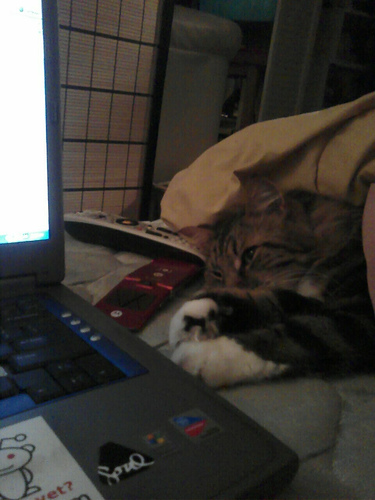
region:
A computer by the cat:
[0, 1, 300, 498]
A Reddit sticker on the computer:
[1, 413, 105, 499]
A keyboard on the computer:
[1, 293, 125, 419]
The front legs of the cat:
[170, 288, 355, 382]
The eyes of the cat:
[213, 245, 258, 278]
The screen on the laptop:
[0, 1, 48, 244]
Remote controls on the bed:
[64, 209, 205, 333]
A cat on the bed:
[166, 167, 373, 383]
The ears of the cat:
[177, 169, 285, 253]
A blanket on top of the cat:
[160, 93, 372, 232]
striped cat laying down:
[177, 186, 351, 361]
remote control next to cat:
[67, 203, 334, 294]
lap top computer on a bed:
[8, 41, 122, 486]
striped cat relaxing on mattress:
[189, 200, 322, 316]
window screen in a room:
[63, 5, 186, 105]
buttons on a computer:
[12, 302, 81, 375]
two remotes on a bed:
[72, 200, 190, 321]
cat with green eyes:
[182, 218, 296, 279]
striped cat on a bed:
[197, 209, 332, 281]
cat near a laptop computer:
[167, 168, 310, 485]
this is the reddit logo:
[0, 431, 39, 497]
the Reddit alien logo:
[1, 428, 39, 498]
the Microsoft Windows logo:
[140, 424, 169, 448]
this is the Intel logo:
[171, 412, 204, 425]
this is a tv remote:
[69, 196, 207, 262]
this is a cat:
[174, 167, 373, 390]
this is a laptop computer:
[0, 1, 298, 499]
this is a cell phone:
[77, 243, 198, 329]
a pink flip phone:
[94, 242, 197, 342]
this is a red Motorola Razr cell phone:
[88, 251, 195, 346]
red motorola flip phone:
[97, 253, 194, 334]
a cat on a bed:
[163, 181, 373, 388]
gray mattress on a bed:
[63, 238, 371, 495]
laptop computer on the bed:
[4, 2, 303, 498]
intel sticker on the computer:
[170, 409, 217, 441]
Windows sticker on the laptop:
[139, 427, 168, 448]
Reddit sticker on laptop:
[1, 421, 102, 499]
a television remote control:
[65, 208, 202, 259]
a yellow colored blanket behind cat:
[163, 96, 374, 240]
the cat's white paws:
[169, 301, 282, 378]